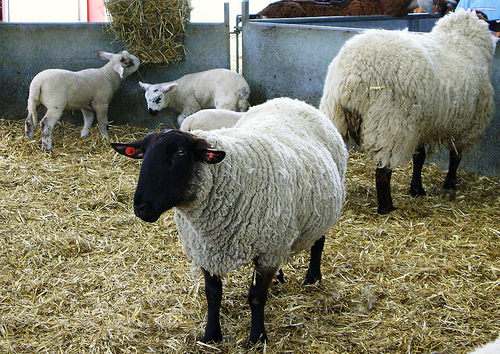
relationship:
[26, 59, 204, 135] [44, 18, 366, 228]
lambs in stall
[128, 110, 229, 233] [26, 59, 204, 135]
head of lambs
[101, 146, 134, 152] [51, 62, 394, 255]
ears on sheep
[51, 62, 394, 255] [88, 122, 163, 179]
sheep have ear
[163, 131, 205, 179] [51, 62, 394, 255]
eye on sheep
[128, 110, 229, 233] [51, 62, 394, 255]
head on sheep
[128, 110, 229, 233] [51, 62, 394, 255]
head of sheep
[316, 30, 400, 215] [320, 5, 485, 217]
backside of a sheep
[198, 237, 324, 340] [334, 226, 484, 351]
sheep's legs standing in hay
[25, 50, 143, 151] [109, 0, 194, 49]
lamb chewing hay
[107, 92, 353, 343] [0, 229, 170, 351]
lamb in hay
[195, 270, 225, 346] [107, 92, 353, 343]
front leg of lamb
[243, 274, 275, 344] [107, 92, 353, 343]
front leg of lamb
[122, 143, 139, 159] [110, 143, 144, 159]
tag on ears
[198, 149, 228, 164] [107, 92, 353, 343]
left ear of lamb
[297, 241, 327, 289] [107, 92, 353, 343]
back leg of lamb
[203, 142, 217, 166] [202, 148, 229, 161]
tag in left ear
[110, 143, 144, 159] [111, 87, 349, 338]
ears of a sheep